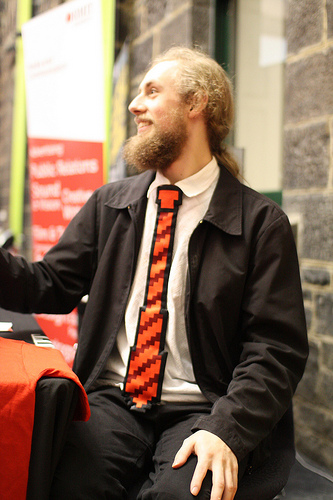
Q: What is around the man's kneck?
A: Tie.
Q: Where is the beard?
A: Man's face.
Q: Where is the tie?
A: Around man's neck.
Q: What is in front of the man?
A: Table.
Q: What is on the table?
A: Shirt.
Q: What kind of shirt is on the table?
A: Short sleeve.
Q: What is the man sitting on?
A: Chair.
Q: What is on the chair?
A: Adult man.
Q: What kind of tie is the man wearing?
A: Pixelated tie.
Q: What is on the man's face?
A: Beard.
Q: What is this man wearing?
A: Suit.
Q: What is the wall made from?
A: Stone bricks.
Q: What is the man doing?
A: Smiling.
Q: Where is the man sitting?
A: Chair.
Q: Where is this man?
A: Restaurant.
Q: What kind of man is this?
A: White.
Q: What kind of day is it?
A: Sunny.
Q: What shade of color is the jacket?
A: Black.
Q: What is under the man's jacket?
A: Shirt.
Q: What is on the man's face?
A: Beard.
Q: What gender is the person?
A: Male.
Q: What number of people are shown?
A: 1.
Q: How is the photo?
A: Clear.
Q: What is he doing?
A: Sitting.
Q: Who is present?
A: A man.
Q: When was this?
A: Daytime.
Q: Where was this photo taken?
A: At a table.